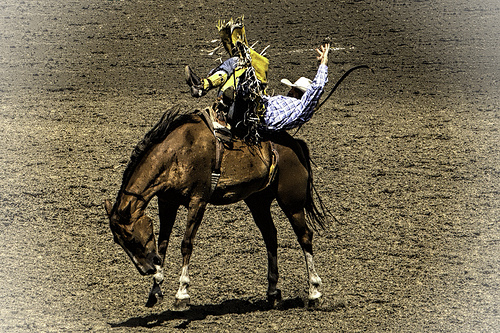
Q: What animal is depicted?
A: Horse.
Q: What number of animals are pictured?
A: 1.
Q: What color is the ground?
A: Brown.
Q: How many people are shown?
A: 1.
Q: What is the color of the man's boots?
A: Yellow.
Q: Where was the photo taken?
A: A rodeo.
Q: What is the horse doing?
A: Bucking.